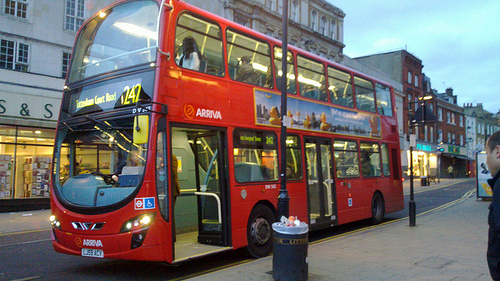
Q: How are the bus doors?
A: Open.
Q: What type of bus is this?
A: Double decker.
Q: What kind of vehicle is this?
A: Bus.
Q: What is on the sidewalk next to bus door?
A: Trashcan.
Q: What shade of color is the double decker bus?
A: Red.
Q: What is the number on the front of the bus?
A: 247.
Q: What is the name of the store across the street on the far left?
A: S&s.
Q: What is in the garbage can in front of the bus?
A: White trash bag liner.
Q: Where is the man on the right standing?
A: Sidewalk.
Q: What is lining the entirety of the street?
A: Store fronts.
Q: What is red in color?
A: The bus.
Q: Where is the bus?
A: On the road.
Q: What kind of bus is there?
A: Double decker.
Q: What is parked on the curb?
A: A bus.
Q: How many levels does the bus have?
A: Two.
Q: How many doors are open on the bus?
A: Two.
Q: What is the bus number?
A: 242.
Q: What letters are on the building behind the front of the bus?
A: S&S.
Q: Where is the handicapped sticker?
A: On front of bus.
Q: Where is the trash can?
A: On sidewalk.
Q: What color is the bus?
A: Red.